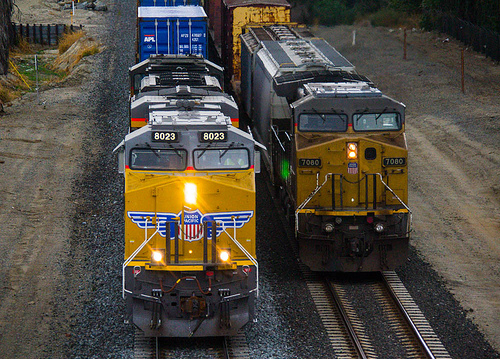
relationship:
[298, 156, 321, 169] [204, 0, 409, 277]
number on train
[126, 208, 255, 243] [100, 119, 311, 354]
logo on train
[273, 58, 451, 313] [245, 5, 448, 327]
train on right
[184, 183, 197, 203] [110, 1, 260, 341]
headlight on train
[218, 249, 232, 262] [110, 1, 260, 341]
light on train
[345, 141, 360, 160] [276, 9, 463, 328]
train light on right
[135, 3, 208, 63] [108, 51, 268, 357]
container on train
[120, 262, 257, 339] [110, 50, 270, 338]
cowcatcher on engine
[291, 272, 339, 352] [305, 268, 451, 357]
section of tracks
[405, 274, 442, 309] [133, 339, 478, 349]
gravel besides train tracks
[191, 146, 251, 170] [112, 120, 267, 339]
window on train front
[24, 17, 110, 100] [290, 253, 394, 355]
debris near tracks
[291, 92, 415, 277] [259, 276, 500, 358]
train engine on train tracks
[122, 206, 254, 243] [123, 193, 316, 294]
logo with wings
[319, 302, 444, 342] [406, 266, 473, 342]
train tracks on ground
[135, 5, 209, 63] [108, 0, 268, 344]
container pulled by train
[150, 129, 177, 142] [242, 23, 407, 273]
numbers on train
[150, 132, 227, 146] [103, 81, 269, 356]
numbers on train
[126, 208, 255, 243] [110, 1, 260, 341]
logo on train